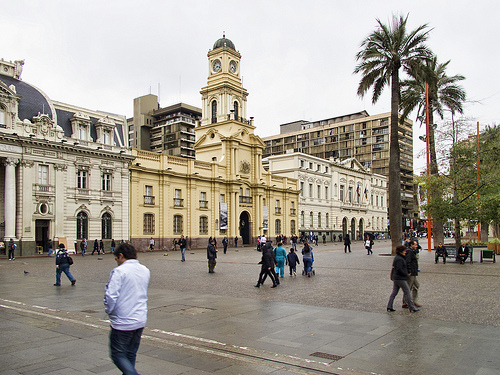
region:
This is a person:
[106, 240, 152, 374]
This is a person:
[199, 235, 221, 277]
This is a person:
[381, 240, 413, 314]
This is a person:
[303, 240, 318, 279]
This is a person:
[341, 230, 352, 253]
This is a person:
[361, 226, 375, 254]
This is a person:
[75, 235, 89, 254]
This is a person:
[91, 234, 100, 256]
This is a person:
[107, 236, 114, 257]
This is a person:
[149, 232, 159, 254]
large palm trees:
[348, 12, 457, 262]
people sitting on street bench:
[436, 238, 473, 265]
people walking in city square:
[13, 232, 452, 373]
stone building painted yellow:
[129, 30, 299, 250]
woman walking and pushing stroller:
[300, 240, 318, 276]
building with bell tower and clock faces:
[129, 30, 299, 249]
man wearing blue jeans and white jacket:
[104, 238, 150, 373]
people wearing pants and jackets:
[251, 238, 439, 310]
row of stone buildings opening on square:
[3, 54, 390, 262]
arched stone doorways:
[228, 203, 372, 245]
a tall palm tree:
[355, 14, 420, 249]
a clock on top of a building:
[205, 54, 242, 71]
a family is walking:
[272, 235, 315, 275]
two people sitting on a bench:
[430, 240, 477, 262]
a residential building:
[267, 107, 412, 159]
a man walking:
[98, 235, 158, 373]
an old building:
[0, 57, 125, 250]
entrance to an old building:
[237, 207, 250, 250]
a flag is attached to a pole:
[357, 184, 369, 201]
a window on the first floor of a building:
[102, 168, 112, 194]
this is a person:
[84, 233, 178, 373]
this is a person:
[226, 187, 283, 299]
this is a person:
[366, 235, 419, 318]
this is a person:
[407, 232, 429, 299]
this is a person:
[48, 223, 85, 288]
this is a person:
[197, 235, 223, 272]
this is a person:
[172, 223, 196, 280]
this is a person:
[344, 220, 355, 260]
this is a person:
[360, 219, 394, 261]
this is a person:
[454, 236, 477, 266]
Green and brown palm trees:
[352, 17, 462, 268]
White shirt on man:
[100, 259, 156, 335]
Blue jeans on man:
[100, 321, 151, 373]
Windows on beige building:
[138, 178, 298, 239]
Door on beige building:
[234, 206, 257, 246]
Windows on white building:
[297, 159, 385, 217]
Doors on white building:
[336, 210, 371, 240]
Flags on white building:
[341, 183, 373, 212]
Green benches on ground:
[427, 242, 498, 264]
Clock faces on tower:
[201, 57, 242, 76]